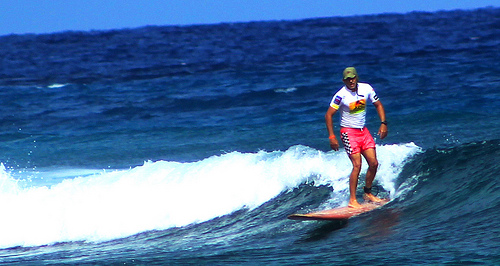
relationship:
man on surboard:
[312, 59, 396, 191] [295, 203, 388, 230]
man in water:
[312, 59, 396, 191] [108, 32, 277, 181]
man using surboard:
[312, 59, 396, 191] [295, 203, 388, 230]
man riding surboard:
[312, 59, 396, 191] [295, 203, 388, 230]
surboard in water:
[295, 203, 388, 230] [108, 32, 277, 181]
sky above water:
[154, 0, 211, 26] [108, 32, 277, 181]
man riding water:
[312, 59, 396, 191] [108, 32, 277, 181]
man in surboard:
[312, 59, 396, 191] [295, 203, 388, 230]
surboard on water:
[295, 203, 388, 230] [108, 32, 277, 181]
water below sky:
[108, 32, 277, 181] [154, 0, 211, 26]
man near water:
[312, 59, 396, 191] [108, 32, 277, 181]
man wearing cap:
[312, 59, 396, 191] [340, 60, 364, 88]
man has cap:
[312, 59, 396, 191] [340, 60, 364, 88]